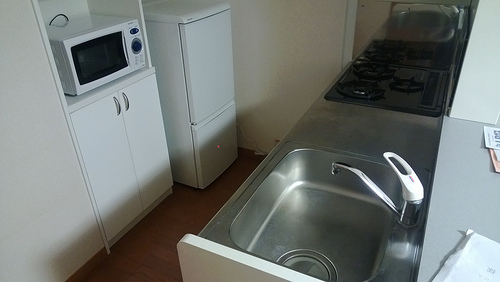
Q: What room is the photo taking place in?
A: Kitchen.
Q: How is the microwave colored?
A: White and black.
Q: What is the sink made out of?
A: Metal.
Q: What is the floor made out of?
A: Wood.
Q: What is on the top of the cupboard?
A: Handles.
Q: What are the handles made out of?
A: Steel.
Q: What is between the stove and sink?
A: Counter.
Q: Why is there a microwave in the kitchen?
A: To heat up the food.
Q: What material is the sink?
A: Stainless steel.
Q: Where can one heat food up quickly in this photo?
A: A microwave.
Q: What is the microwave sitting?
A: On top of cabinet.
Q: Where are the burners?
A: On stove.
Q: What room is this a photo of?
A: Kitchen.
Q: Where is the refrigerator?
A: In corner.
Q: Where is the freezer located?
A: Bottom of refrigerator.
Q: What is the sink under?
A: A window.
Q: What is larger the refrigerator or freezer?
A: The refrigerator.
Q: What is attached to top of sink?
A: A faucet.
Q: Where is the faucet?
A: On the sink.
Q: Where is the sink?
A: Under the faucet.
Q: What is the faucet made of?
A: Metal.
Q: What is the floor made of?
A: Wood.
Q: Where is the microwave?
A: On the cabinets.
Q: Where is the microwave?
A: Over the cabinet.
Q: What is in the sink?
A: It's empty.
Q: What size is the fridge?
A: Small.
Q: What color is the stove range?
A: Black.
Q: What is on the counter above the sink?
A: Papers.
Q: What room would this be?
A: A kitchen.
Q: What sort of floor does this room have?
A: Wood.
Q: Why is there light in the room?
A: The window is open.